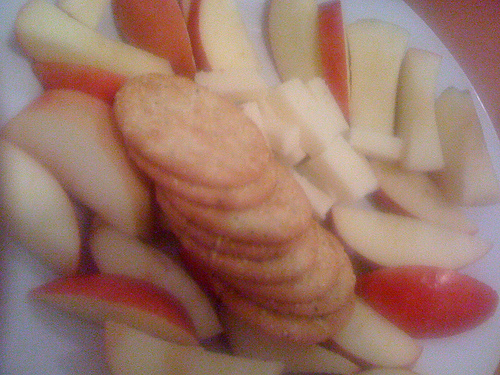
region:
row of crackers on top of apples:
[108, 65, 369, 349]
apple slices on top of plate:
[3, 1, 496, 373]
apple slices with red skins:
[3, 3, 498, 374]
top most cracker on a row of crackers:
[107, 69, 274, 191]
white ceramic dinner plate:
[2, 2, 498, 374]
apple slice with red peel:
[353, 261, 498, 341]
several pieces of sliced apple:
[3, 4, 495, 374]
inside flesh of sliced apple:
[337, 200, 487, 261]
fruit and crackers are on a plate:
[5, 5, 499, 372]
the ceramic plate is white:
[5, 2, 499, 369]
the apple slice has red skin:
[358, 264, 499, 339]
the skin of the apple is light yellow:
[17, 85, 154, 231]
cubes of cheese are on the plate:
[200, 63, 377, 225]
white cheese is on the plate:
[203, 69, 384, 211]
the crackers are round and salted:
[108, 65, 368, 346]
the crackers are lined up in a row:
[113, 69, 360, 348]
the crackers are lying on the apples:
[77, 62, 378, 352]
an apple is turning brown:
[94, 317, 214, 374]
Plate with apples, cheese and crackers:
[2, 3, 499, 372]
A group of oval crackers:
[111, 70, 359, 343]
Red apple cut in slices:
[3, 1, 499, 373]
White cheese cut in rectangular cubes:
[192, 59, 402, 219]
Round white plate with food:
[6, 2, 499, 372]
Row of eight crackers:
[111, 74, 358, 343]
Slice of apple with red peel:
[356, 264, 498, 336]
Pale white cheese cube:
[308, 137, 381, 203]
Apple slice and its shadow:
[21, 274, 199, 358]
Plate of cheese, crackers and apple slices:
[5, 4, 498, 371]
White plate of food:
[0, 0, 496, 370]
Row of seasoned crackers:
[112, 70, 358, 344]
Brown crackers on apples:
[114, 70, 358, 344]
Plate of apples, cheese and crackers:
[0, 0, 497, 373]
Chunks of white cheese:
[191, 64, 399, 222]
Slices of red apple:
[2, 2, 499, 374]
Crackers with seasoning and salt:
[115, 68, 357, 343]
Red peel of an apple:
[355, 260, 497, 341]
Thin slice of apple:
[317, 2, 350, 122]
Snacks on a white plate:
[1, 0, 498, 372]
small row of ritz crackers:
[110, 70, 365, 345]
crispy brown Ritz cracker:
[109, 70, 281, 189]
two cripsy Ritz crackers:
[114, 68, 281, 210]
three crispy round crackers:
[113, 70, 318, 241]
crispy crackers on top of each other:
[110, 68, 362, 346]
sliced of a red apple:
[37, 269, 205, 344]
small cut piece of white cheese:
[347, 125, 405, 163]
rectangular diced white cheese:
[238, 72, 409, 219]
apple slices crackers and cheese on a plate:
[0, 0, 499, 374]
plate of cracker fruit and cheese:
[2, 1, 499, 373]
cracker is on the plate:
[112, 72, 270, 187]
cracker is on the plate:
[163, 160, 313, 242]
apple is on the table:
[1, 87, 151, 242]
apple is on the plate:
[355, 262, 498, 339]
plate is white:
[2, 0, 498, 372]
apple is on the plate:
[188, 0, 260, 77]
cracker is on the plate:
[224, 221, 342, 304]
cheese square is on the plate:
[351, 126, 403, 161]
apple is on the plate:
[0, 137, 80, 280]